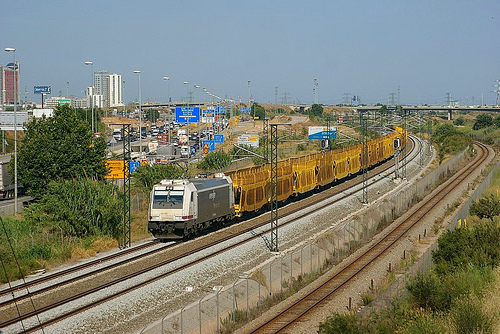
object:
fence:
[137, 144, 473, 331]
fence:
[62, 143, 334, 201]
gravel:
[248, 219, 343, 267]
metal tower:
[270, 124, 279, 252]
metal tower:
[361, 119, 369, 204]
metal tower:
[122, 123, 131, 249]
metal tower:
[401, 117, 408, 178]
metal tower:
[263, 119, 269, 163]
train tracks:
[250, 140, 488, 334]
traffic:
[143, 137, 198, 162]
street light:
[4, 47, 17, 53]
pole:
[14, 51, 18, 215]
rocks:
[187, 267, 219, 282]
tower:
[260, 115, 301, 255]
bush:
[444, 287, 500, 334]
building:
[106, 72, 125, 108]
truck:
[157, 140, 177, 159]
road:
[102, 140, 192, 160]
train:
[146, 126, 407, 243]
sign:
[179, 104, 201, 119]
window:
[151, 194, 183, 209]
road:
[97, 115, 220, 182]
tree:
[396, 231, 498, 314]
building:
[93, 69, 110, 109]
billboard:
[308, 125, 337, 140]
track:
[0, 133, 490, 334]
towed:
[146, 125, 408, 242]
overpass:
[138, 102, 498, 115]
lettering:
[129, 162, 141, 172]